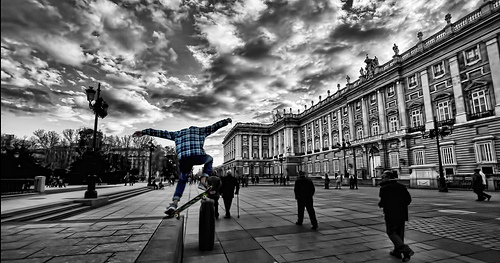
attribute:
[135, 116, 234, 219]
boy — skating, young, boarding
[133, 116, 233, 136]
hands — long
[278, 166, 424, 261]
people — walking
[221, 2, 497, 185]
building — beside, large, tall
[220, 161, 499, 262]
people — beside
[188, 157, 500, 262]
street — wide, paved, brick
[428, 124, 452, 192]
light — black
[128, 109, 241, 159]
shirt — blue, striped, plaid, bright, black, checkered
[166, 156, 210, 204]
trousers — folded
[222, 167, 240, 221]
man — walking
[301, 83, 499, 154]
windows — arched, above, large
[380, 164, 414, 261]
man — bald, walking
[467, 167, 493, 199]
people — walking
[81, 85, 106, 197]
pole — black, tall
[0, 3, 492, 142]
clouds — grey, cloudy, gray, white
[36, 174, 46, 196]
can — white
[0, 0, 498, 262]
photo — black-white